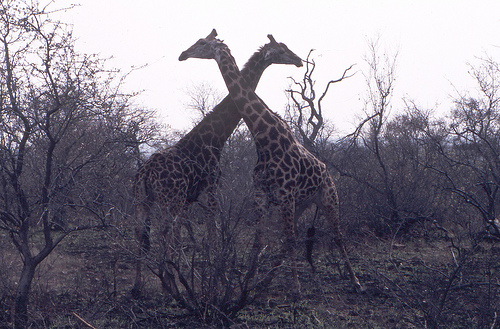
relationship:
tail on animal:
[139, 147, 160, 250] [175, 28, 367, 306]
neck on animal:
[223, 67, 268, 130] [175, 28, 367, 306]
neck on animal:
[212, 54, 279, 155] [131, 34, 303, 304]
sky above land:
[2, 1, 484, 160] [4, 207, 494, 326]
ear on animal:
[264, 47, 278, 61] [175, 28, 367, 308]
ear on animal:
[203, 27, 218, 39] [125, 33, 303, 297]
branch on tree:
[35, 203, 126, 293] [23, 37, 115, 144]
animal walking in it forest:
[175, 28, 367, 306] [59, 8, 429, 305]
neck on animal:
[218, 52, 293, 153] [175, 28, 367, 306]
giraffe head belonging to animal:
[178, 28, 226, 61] [175, 28, 367, 306]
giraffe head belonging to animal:
[253, 34, 304, 70] [131, 34, 303, 304]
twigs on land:
[351, 252, 499, 319] [0, 207, 500, 329]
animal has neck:
[175, 28, 367, 306] [211, 60, 287, 137]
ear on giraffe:
[262, 31, 285, 51] [236, 16, 311, 98]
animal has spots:
[131, 34, 303, 304] [138, 53, 267, 210]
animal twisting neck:
[175, 28, 367, 306] [184, 49, 268, 153]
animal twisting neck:
[175, 28, 367, 306] [204, 50, 264, 174]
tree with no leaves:
[0, 1, 137, 327] [44, 102, 461, 152]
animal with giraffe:
[175, 28, 367, 306] [97, 30, 305, 284]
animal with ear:
[175, 28, 367, 306] [264, 47, 278, 61]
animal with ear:
[175, 28, 367, 306] [205, 28, 218, 39]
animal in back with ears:
[175, 28, 367, 306] [207, 28, 221, 43]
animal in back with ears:
[131, 34, 303, 304] [262, 31, 279, 47]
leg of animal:
[278, 195, 302, 299] [175, 28, 367, 306]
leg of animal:
[326, 197, 363, 296] [175, 28, 367, 308]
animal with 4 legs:
[175, 28, 367, 306] [238, 192, 362, 298]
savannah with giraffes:
[5, 2, 482, 312] [113, 28, 334, 276]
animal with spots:
[175, 28, 367, 306] [206, 36, 341, 246]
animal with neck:
[131, 34, 303, 304] [214, 67, 278, 131]